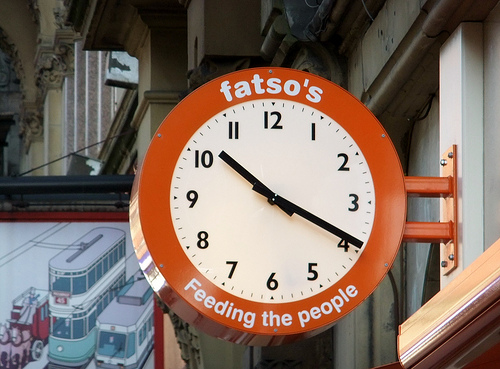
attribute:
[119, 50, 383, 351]
clock — orange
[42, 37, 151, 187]
columns — tan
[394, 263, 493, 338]
side trim — wooden